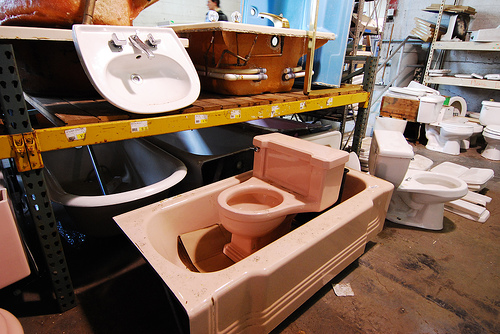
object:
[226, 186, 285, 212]
sink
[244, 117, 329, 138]
bathtub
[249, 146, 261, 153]
handle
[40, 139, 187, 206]
bathtub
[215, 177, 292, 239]
tub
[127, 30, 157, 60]
faucet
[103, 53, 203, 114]
sink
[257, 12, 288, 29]
faucet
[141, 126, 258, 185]
bathtub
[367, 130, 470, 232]
toilet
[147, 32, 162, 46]
knob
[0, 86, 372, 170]
shelf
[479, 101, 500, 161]
toilet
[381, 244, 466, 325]
floor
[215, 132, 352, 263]
toilet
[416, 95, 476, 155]
toilet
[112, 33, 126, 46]
handles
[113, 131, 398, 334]
bath tub